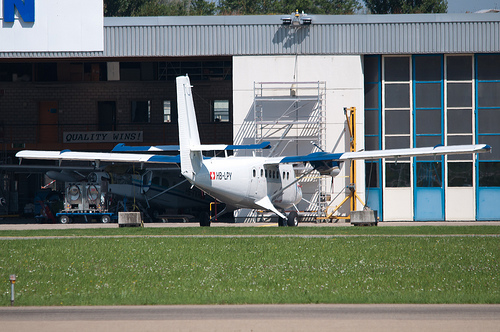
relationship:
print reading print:
[105, 127, 143, 144] [110, 132, 143, 142]